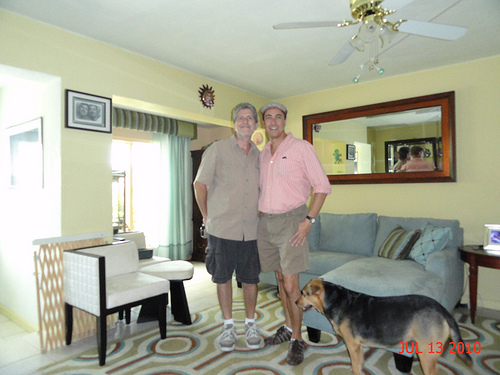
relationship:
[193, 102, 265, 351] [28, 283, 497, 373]
carpet under man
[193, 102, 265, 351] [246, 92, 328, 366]
carpet under man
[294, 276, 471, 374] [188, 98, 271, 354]
dog near guys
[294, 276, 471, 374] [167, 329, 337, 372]
dog atop carpet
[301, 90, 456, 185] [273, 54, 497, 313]
mirror on wall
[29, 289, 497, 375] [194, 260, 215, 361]
carpet on floor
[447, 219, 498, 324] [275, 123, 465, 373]
table near sofa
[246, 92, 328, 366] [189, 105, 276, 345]
man near man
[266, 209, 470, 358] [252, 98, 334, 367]
couch behind man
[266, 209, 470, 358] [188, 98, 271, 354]
couch behind guys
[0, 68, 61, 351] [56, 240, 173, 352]
gate behind chair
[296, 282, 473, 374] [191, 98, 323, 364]
dog next to men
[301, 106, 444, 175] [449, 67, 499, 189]
mirror on wall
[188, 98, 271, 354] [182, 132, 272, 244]
guys wearing shirt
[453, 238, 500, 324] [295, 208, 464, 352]
table beside gray couch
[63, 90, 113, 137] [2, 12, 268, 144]
picture on wall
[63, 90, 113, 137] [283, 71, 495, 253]
picture on wall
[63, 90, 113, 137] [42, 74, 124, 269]
picture on wall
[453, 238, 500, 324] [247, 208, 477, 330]
table by couch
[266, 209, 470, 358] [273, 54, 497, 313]
couch by wall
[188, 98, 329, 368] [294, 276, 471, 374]
guys and dog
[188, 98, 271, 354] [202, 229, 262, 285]
guys in black shorts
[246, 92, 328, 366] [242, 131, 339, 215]
man in shirt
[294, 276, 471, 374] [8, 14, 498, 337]
dog in living room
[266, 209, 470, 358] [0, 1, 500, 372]
couch in living room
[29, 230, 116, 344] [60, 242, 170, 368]
gate behind chair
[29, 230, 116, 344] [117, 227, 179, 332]
gate behind chair